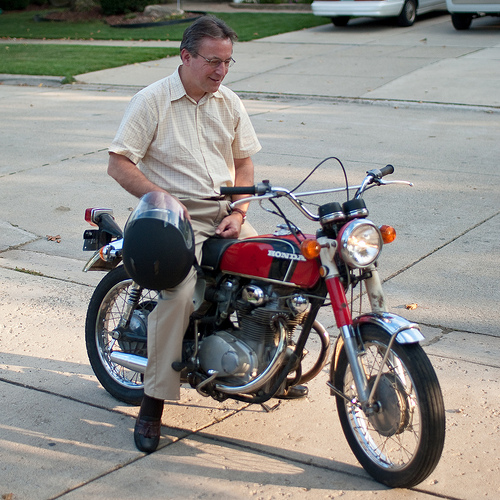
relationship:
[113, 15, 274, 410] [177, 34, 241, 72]
man wears glasses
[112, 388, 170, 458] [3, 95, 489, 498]
shoe on pavement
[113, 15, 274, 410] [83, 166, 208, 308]
biker holding helmet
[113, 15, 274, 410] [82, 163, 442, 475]
man on motorcycle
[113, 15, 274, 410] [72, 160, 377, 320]
man looking down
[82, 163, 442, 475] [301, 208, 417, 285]
motorcycle has headlight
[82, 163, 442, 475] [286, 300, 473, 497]
motorcycle has wheel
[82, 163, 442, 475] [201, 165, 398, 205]
motorcycle has handlebars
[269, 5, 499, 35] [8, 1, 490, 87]
cars in background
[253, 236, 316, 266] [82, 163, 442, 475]
honda on motorcycle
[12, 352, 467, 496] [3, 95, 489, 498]
shadow on pavement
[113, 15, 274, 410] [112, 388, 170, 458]
man has shoe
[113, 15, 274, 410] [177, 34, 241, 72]
man has glasses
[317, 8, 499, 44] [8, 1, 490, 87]
vehicles in background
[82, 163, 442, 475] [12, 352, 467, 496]
motorcycle has shadow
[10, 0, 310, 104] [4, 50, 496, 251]
lawn on street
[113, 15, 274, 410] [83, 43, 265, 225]
man wears shirt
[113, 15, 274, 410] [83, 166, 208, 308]
man has helmet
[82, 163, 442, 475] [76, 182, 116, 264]
motorcycle has tail lights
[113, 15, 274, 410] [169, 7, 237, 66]
man has hair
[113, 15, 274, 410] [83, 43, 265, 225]
man has shirt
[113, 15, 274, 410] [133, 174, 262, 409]
man has pants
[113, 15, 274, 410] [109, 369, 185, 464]
man has shoes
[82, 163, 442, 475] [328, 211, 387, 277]
bike has light